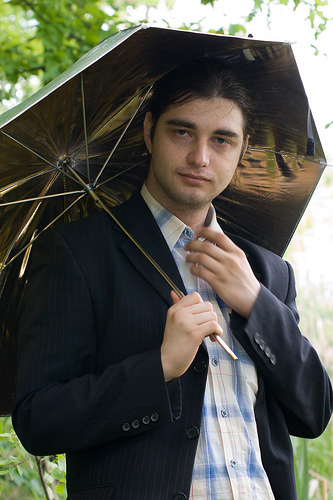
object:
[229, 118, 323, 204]
reflection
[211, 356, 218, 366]
buttons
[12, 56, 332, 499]
man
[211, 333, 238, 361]
handle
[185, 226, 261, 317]
hand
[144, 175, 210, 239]
neck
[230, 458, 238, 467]
buttons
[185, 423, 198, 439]
button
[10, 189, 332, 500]
jacket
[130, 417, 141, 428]
buttons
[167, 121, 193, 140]
eyes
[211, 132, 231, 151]
eyes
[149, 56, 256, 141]
brown hair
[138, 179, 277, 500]
shirt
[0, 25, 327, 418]
umbrella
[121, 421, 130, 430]
buttons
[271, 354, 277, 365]
buttons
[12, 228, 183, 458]
sleeve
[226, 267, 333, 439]
sleeve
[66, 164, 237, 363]
umbrella handle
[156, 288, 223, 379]
hand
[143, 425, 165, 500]
pin stripes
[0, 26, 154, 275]
shadow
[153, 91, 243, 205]
face